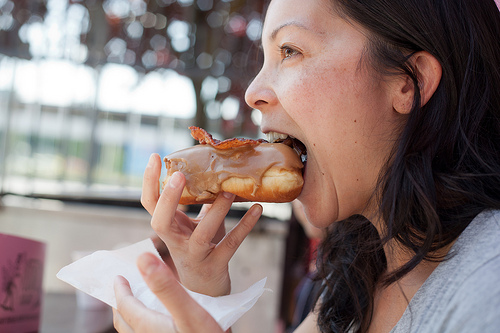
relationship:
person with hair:
[182, 15, 482, 315] [390, 75, 459, 225]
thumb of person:
[127, 240, 204, 327] [94, 20, 480, 304]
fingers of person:
[167, 121, 270, 311] [154, 26, 468, 303]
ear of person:
[366, 29, 445, 137] [194, 32, 463, 331]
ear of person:
[393, 51, 443, 114] [136, 10, 468, 304]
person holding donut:
[112, 0, 500, 333] [158, 131, 306, 263]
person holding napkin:
[112, 0, 500, 333] [65, 224, 297, 324]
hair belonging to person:
[302, 0, 500, 333] [112, 0, 500, 333]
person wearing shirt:
[112, 0, 500, 333] [388, 206, 485, 330]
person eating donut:
[112, 0, 500, 333] [162, 121, 306, 204]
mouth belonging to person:
[258, 124, 308, 196] [112, 0, 500, 333]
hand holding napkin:
[110, 250, 225, 331] [53, 236, 274, 331]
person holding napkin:
[112, 0, 500, 333] [53, 236, 274, 331]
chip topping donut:
[187, 122, 268, 150] [162, 121, 306, 204]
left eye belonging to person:
[278, 41, 305, 64] [112, 0, 500, 333]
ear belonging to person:
[393, 51, 443, 114] [112, 0, 500, 333]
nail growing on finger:
[168, 170, 183, 189] [148, 170, 187, 250]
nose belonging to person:
[242, 56, 277, 110] [112, 0, 500, 333]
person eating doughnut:
[112, 0, 500, 333] [161, 122, 305, 204]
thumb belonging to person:
[132, 250, 217, 331] [112, 0, 500, 333]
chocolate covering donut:
[163, 139, 304, 206] [162, 121, 306, 204]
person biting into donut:
[112, 0, 500, 333] [162, 121, 306, 204]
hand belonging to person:
[110, 250, 225, 331] [112, 0, 500, 333]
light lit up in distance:
[168, 32, 190, 52] [0, 0, 290, 226]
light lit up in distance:
[105, 37, 126, 56] [0, 0, 290, 226]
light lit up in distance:
[66, 3, 87, 23] [0, 0, 290, 226]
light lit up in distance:
[167, 19, 190, 51] [0, 0, 290, 226]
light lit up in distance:
[227, 12, 247, 33] [0, 0, 290, 226]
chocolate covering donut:
[161, 141, 304, 196] [162, 121, 306, 204]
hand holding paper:
[110, 250, 225, 331] [53, 236, 273, 331]